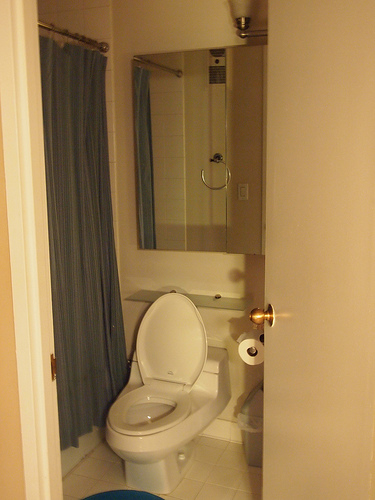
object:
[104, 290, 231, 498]
toilet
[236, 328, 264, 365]
toilet paper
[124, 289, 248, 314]
shelf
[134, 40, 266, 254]
mirror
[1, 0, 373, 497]
bathroom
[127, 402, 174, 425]
toilet bowl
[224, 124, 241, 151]
ground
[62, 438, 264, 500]
tile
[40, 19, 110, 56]
rod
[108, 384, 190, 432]
seat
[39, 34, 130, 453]
shower curtain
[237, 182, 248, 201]
light switch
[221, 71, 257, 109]
ground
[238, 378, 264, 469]
garbage can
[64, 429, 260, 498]
floor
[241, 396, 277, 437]
trashbag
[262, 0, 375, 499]
door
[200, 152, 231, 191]
ring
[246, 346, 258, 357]
holder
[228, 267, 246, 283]
shadow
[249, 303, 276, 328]
doorknob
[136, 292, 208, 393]
lid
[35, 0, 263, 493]
room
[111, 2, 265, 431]
wall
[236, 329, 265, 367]
roll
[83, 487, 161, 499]
bath mat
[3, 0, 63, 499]
bathroom frame